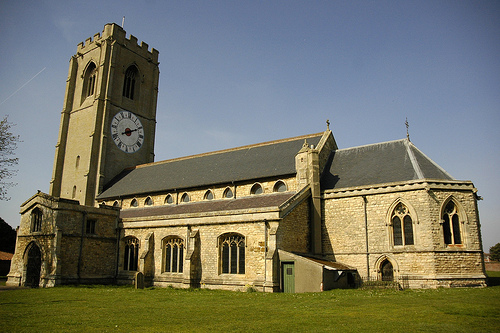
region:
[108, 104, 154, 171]
tower clock on building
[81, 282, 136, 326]
grass outside of building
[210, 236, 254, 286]
windows of chapel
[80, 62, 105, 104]
higher chapel windows of chapel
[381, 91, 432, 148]
crucifix on top of chapel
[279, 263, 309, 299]
side door to chapel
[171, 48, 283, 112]
dark blue sky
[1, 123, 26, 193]
tall tree on side of chapel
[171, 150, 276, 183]
gray roof of chapel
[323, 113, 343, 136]
another crucifix on top of chapel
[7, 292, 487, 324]
the grass is green and smooth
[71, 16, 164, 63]
the roof looks like a castle top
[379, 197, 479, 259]
the building has windows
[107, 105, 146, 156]
a huge white clock on the building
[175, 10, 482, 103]
a clear blue sky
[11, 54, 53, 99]
a jet flying far away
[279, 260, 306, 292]
a tiny green door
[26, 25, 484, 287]
a small tan building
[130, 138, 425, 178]
a black roof top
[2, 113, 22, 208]
a short tree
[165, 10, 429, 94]
this is the sky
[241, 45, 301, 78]
the sky is blue in color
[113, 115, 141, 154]
this is a clock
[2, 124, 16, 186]
this is a tree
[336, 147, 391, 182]
this is a roof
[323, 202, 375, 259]
this is a wall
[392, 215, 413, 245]
this is a window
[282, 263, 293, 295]
this is a door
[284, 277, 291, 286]
the door is green in color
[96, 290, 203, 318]
this is a grass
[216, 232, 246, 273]
the window on a building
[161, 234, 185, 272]
the window on a building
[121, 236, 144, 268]
the window on a building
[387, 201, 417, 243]
the window on a building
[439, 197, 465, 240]
the window on a building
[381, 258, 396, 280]
the window on a building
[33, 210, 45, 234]
the window on a building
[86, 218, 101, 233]
the window on a building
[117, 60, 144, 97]
the window on a building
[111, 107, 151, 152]
a white clock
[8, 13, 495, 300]
a stone church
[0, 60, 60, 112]
an airplane trail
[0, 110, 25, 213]
tree branches without leaves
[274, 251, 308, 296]
a green wooden door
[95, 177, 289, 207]
ten half circle windows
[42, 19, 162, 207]
a white clock on tower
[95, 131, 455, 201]
two black roofs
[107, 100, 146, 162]
a white clock with roman numerals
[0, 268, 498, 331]
the grass is green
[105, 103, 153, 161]
a white clock with a red center